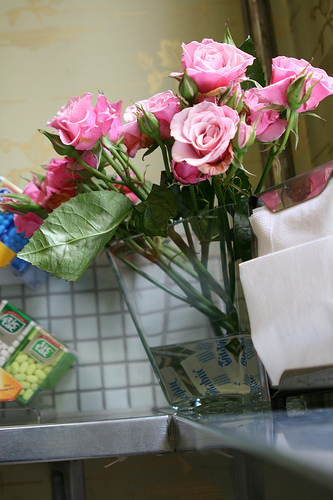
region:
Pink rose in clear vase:
[167, 101, 239, 182]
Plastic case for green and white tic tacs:
[0, 296, 75, 403]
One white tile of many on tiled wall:
[99, 384, 130, 412]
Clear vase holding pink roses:
[101, 200, 268, 413]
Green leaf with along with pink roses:
[16, 189, 127, 283]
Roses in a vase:
[0, 25, 331, 415]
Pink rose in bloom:
[168, 99, 238, 176]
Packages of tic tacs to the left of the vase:
[0, 300, 75, 403]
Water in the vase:
[149, 333, 274, 407]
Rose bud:
[285, 63, 322, 134]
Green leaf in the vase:
[16, 187, 133, 283]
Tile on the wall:
[0, 226, 230, 425]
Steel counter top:
[2, 405, 331, 482]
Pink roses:
[0, 34, 332, 234]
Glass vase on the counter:
[109, 200, 276, 416]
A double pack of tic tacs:
[0, 300, 77, 405]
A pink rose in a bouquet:
[173, 102, 239, 180]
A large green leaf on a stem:
[15, 193, 137, 284]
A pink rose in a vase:
[168, 38, 255, 96]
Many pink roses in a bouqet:
[7, 26, 331, 278]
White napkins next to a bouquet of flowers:
[247, 177, 331, 258]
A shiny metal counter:
[0, 404, 332, 478]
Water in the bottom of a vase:
[152, 327, 265, 407]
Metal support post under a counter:
[50, 462, 91, 499]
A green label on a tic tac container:
[30, 339, 56, 358]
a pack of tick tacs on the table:
[0, 297, 73, 408]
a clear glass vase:
[104, 208, 272, 420]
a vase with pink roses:
[0, 35, 332, 413]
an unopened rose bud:
[131, 98, 160, 146]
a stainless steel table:
[0, 408, 188, 465]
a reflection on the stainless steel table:
[190, 406, 332, 477]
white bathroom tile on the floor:
[74, 283, 147, 410]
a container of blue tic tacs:
[1, 174, 28, 276]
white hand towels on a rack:
[249, 206, 331, 358]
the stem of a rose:
[215, 175, 239, 337]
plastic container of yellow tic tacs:
[1, 319, 75, 405]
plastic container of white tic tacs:
[0, 297, 35, 362]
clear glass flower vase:
[99, 199, 274, 412]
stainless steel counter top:
[0, 403, 329, 494]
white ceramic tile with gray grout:
[68, 309, 99, 341]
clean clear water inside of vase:
[143, 330, 268, 411]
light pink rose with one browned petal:
[166, 96, 236, 182]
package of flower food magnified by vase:
[180, 336, 248, 394]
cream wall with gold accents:
[0, 0, 268, 190]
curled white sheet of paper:
[237, 230, 329, 383]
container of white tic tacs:
[1, 295, 33, 370]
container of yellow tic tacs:
[5, 328, 65, 406]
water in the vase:
[150, 331, 255, 409]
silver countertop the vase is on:
[2, 397, 329, 493]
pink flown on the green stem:
[11, 199, 40, 240]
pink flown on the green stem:
[47, 89, 115, 147]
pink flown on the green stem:
[129, 87, 176, 146]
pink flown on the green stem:
[42, 149, 91, 191]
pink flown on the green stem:
[16, 179, 54, 224]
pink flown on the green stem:
[176, 38, 253, 102]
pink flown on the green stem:
[265, 53, 329, 119]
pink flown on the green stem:
[235, 79, 287, 152]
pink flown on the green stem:
[104, 166, 143, 213]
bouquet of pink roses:
[2, 29, 331, 243]